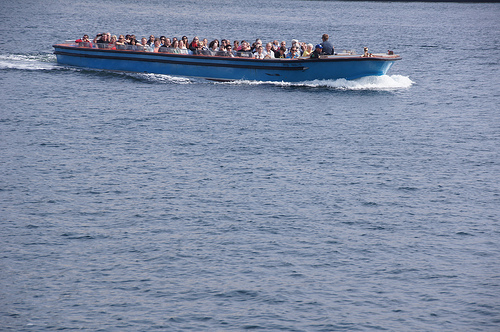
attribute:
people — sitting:
[130, 39, 276, 49]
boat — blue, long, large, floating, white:
[58, 50, 401, 86]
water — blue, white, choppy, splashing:
[346, 75, 426, 94]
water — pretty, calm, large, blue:
[32, 76, 499, 237]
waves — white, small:
[6, 47, 53, 75]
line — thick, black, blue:
[56, 59, 310, 76]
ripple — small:
[98, 167, 227, 230]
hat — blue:
[313, 51, 322, 52]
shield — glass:
[118, 45, 223, 59]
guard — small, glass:
[172, 44, 279, 63]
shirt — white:
[259, 52, 274, 57]